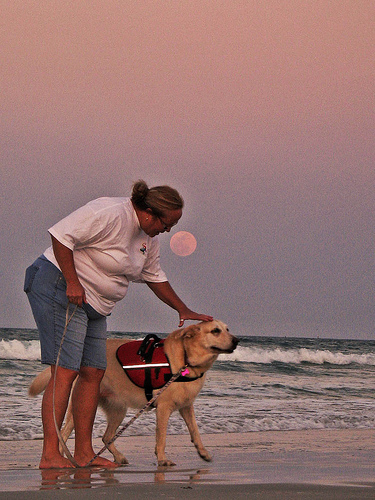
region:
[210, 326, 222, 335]
black dog eye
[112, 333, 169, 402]
red and black harness on dog's body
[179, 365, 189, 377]
pink dog tag shaped like a bone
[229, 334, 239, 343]
black dog nose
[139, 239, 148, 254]
small colorful design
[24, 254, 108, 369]
light blue jean shorts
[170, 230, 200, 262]
moon in the sky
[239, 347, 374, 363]
white foam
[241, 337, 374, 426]
blue water with white foam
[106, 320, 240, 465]
tan dog wearing a red harness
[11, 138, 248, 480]
woman and dog on a beach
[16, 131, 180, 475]
woman in a white t-shirt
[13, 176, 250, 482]
woman petting a dog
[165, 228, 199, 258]
full moon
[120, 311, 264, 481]
dog on a beach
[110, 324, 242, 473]
dog with a red harness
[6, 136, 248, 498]
woman petting a yellow dog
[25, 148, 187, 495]
woman wearing jean shorts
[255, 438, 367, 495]
beach sand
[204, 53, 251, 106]
part of the sky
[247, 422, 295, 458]
edge of a shore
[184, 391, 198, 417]
chest of a dog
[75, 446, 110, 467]
edge of a leg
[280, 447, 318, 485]
part of a shore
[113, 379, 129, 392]
part of a stomach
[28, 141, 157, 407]
this is a lady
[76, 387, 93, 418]
the lady is light skinned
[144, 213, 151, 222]
this is a ear band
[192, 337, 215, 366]
the dog is brown in color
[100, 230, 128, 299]
this is a t shirt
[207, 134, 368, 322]
this is the sky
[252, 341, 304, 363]
these are the waves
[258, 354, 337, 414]
this is a water body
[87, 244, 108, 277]
the t shirt is white in color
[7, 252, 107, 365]
woman wearing blue shorts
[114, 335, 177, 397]
red pack on dog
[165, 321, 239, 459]
brown dog at beach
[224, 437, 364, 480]
brown wet sand at beach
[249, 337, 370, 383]
blue and white waves in ocean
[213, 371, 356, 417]
blue and white waves in ocean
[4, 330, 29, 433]
blue and white waves in ocean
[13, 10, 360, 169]
pink sky at sunset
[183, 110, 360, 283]
pink sky at sunset